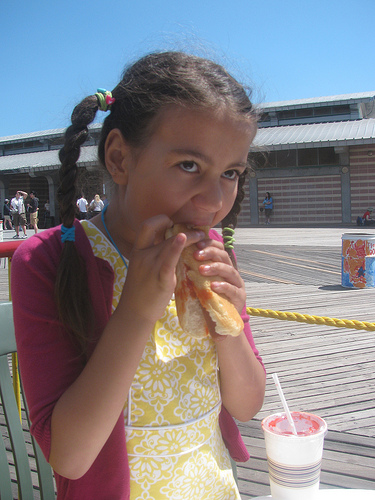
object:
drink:
[260, 407, 326, 500]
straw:
[272, 372, 297, 433]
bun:
[164, 223, 245, 338]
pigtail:
[51, 90, 111, 364]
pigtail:
[221, 173, 246, 268]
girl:
[11, 50, 266, 500]